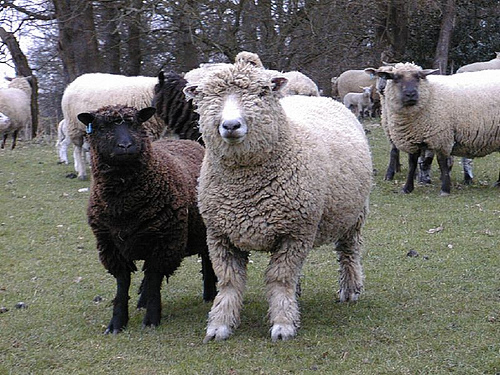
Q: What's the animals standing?
A: Sheep.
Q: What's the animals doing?
A: Standing.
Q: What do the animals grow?
A: Wool.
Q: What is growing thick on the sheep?
A: Wool.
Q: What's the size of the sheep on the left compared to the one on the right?
A: Small.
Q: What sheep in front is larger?
A: Right sheep.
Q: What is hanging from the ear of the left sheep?
A: Tag.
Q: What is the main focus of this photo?
A: Farm animals.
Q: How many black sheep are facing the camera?
A: One.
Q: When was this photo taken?
A: Outside, during the daytime.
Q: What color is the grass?
A: Green.